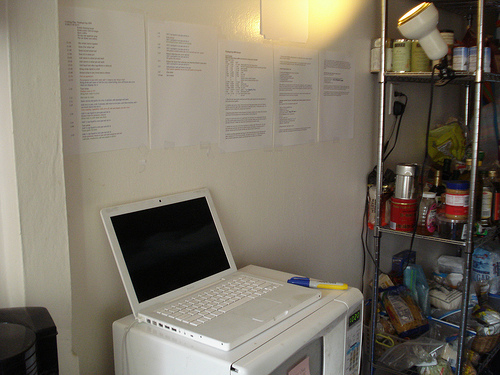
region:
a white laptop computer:
[98, 184, 323, 351]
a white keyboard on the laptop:
[151, 271, 286, 328]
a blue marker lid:
[284, 272, 311, 284]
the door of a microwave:
[228, 299, 347, 374]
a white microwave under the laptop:
[106, 262, 366, 374]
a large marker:
[284, 272, 351, 294]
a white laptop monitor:
[91, 185, 237, 316]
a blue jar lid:
[443, 179, 470, 191]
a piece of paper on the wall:
[215, 36, 276, 156]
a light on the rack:
[390, 1, 456, 65]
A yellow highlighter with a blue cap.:
[289, 274, 351, 291]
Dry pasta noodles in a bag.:
[383, 288, 428, 342]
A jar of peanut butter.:
[445, 181, 469, 218]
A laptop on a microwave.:
[93, 183, 366, 373]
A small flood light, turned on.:
[394, 4, 447, 67]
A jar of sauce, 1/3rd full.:
[415, 190, 440, 236]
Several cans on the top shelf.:
[454, 44, 493, 71]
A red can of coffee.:
[388, 194, 416, 232]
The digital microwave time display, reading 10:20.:
[346, 307, 361, 327]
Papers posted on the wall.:
[61, 13, 356, 150]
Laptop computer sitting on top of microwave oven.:
[96, 178, 323, 350]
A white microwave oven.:
[116, 266, 376, 373]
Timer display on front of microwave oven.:
[346, 302, 368, 331]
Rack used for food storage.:
[370, 6, 496, 374]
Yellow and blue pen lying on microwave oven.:
[284, 271, 350, 301]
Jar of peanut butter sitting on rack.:
[440, 178, 472, 223]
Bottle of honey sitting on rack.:
[415, 186, 441, 238]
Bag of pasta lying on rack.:
[381, 286, 436, 345]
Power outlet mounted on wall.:
[382, 81, 411, 123]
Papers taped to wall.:
[64, 3, 349, 159]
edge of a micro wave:
[350, 346, 362, 360]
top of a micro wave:
[292, 335, 305, 359]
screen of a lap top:
[177, 240, 192, 268]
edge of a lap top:
[117, 230, 119, 254]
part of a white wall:
[280, 155, 305, 220]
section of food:
[426, 185, 465, 243]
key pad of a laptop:
[227, 277, 242, 302]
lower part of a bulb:
[427, 28, 446, 54]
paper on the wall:
[257, 95, 287, 131]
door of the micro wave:
[310, 330, 329, 366]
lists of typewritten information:
[58, 3, 358, 156]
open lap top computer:
[96, 183, 325, 353]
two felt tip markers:
[286, 273, 351, 290]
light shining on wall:
[222, 1, 452, 58]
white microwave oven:
[109, 263, 365, 373]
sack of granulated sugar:
[469, 244, 498, 296]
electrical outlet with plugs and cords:
[358, 78, 420, 290]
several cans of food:
[369, 29, 491, 75]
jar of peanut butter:
[442, 178, 471, 220]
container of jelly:
[417, 188, 439, 234]